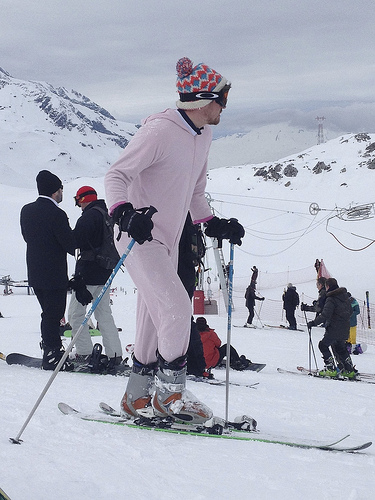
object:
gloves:
[111, 202, 152, 244]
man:
[104, 58, 246, 423]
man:
[19, 169, 77, 369]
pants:
[34, 286, 66, 344]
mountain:
[0, 64, 143, 188]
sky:
[0, 0, 375, 137]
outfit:
[21, 194, 78, 291]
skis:
[57, 402, 371, 452]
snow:
[0, 64, 375, 500]